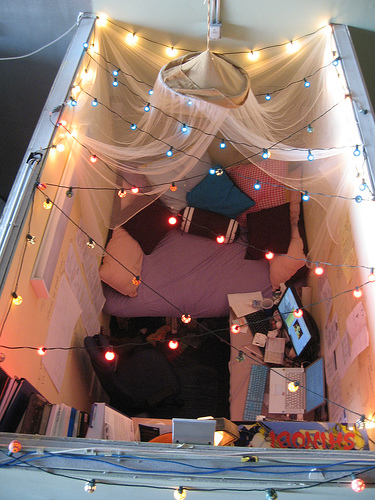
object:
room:
[17, 221, 337, 477]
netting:
[63, 113, 357, 198]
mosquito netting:
[59, 24, 367, 251]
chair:
[82, 336, 184, 414]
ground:
[315, 75, 330, 112]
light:
[130, 184, 141, 197]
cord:
[105, 154, 252, 250]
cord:
[115, 258, 235, 349]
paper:
[339, 251, 359, 284]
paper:
[344, 302, 372, 365]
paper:
[314, 280, 333, 326]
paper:
[322, 312, 338, 359]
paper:
[336, 332, 355, 380]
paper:
[325, 345, 344, 386]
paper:
[325, 377, 342, 416]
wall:
[298, 26, 373, 420]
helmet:
[4, 371, 34, 428]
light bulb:
[299, 190, 310, 201]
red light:
[215, 231, 226, 244]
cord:
[204, 163, 351, 207]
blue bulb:
[218, 136, 232, 150]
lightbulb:
[291, 302, 303, 321]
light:
[261, 89, 274, 103]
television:
[239, 357, 267, 425]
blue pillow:
[185, 162, 256, 214]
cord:
[235, 205, 375, 287]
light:
[90, 98, 99, 108]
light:
[302, 78, 312, 89]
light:
[304, 125, 317, 134]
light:
[262, 144, 272, 159]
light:
[169, 181, 179, 195]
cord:
[35, 175, 104, 250]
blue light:
[250, 178, 262, 191]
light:
[264, 249, 275, 261]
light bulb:
[249, 176, 268, 199]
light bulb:
[165, 144, 176, 161]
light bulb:
[262, 91, 275, 105]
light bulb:
[91, 98, 102, 111]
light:
[166, 214, 178, 226]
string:
[1, 10, 374, 431]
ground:
[249, 76, 273, 99]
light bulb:
[288, 40, 300, 56]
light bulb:
[246, 48, 258, 61]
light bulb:
[214, 234, 224, 244]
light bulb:
[311, 267, 324, 281]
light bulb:
[103, 348, 115, 359]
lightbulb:
[90, 98, 98, 106]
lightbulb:
[179, 123, 187, 133]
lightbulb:
[129, 122, 137, 128]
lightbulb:
[260, 153, 269, 159]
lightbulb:
[303, 149, 315, 161]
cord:
[101, 17, 335, 48]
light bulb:
[210, 167, 215, 175]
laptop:
[269, 357, 326, 415]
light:
[101, 342, 119, 363]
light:
[165, 335, 181, 352]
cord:
[46, 326, 222, 360]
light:
[213, 231, 227, 244]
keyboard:
[242, 361, 268, 422]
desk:
[226, 289, 322, 421]